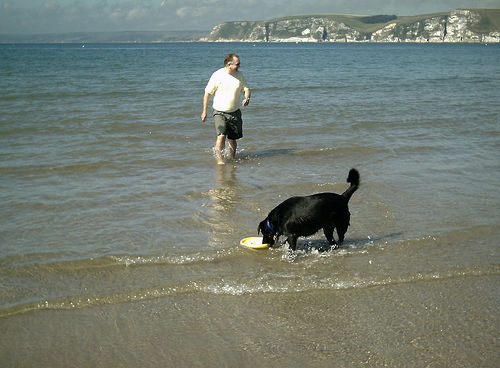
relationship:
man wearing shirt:
[197, 52, 252, 166] [207, 64, 252, 111]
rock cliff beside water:
[233, 20, 457, 50] [270, 47, 495, 144]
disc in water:
[240, 235, 267, 248] [1, 43, 499, 316]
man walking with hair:
[197, 46, 254, 164] [226, 41, 241, 70]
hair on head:
[226, 41, 241, 70] [220, 48, 245, 74]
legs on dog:
[322, 227, 334, 247] [255, 166, 360, 251]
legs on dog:
[336, 224, 348, 244] [255, 166, 360, 251]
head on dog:
[251, 212, 278, 249] [249, 161, 366, 252]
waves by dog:
[3, 217, 498, 322] [254, 158, 360, 253]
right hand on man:
[193, 107, 210, 126] [193, 51, 258, 168]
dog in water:
[254, 167, 381, 265] [19, 180, 231, 251]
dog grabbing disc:
[255, 166, 360, 251] [239, 234, 269, 251]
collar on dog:
[262, 215, 274, 232] [255, 166, 360, 251]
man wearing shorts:
[197, 52, 252, 166] [209, 108, 251, 142]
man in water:
[197, 52, 252, 166] [0, 44, 498, 365]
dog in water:
[255, 166, 360, 251] [0, 44, 498, 365]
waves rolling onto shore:
[0, 205, 499, 320] [0, 243, 495, 365]